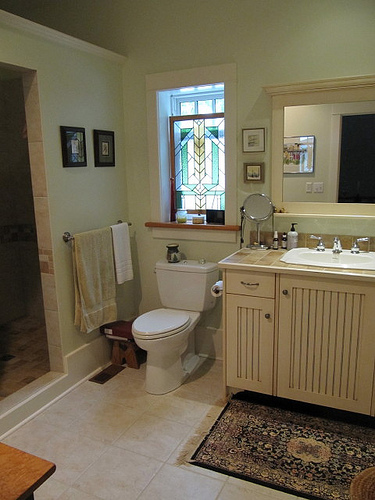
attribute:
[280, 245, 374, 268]
sink — bathroom sink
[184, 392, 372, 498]
rug — area rug